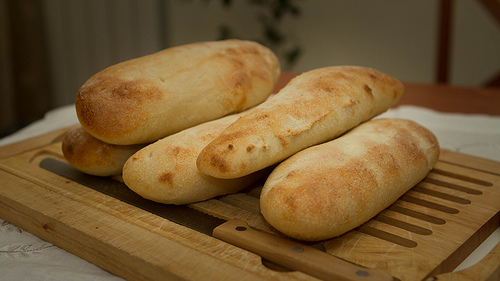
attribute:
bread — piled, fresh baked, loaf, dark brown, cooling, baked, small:
[74, 37, 282, 145]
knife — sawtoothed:
[40, 156, 393, 280]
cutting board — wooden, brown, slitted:
[0, 121, 500, 280]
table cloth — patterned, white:
[1, 99, 499, 280]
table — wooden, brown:
[256, 68, 499, 116]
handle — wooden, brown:
[428, 236, 499, 279]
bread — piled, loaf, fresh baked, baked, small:
[259, 114, 441, 242]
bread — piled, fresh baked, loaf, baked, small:
[195, 63, 405, 179]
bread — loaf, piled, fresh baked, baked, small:
[122, 98, 285, 206]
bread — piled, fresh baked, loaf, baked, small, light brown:
[62, 124, 150, 177]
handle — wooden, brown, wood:
[212, 216, 394, 280]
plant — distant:
[211, 2, 304, 73]